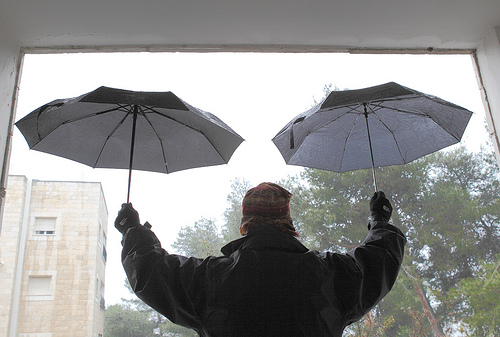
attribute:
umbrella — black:
[13, 86, 245, 226]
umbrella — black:
[270, 81, 473, 226]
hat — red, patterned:
[239, 182, 299, 238]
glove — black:
[368, 190, 394, 228]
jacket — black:
[119, 221, 406, 336]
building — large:
[0, 174, 109, 335]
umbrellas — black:
[13, 80, 474, 206]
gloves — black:
[114, 190, 393, 234]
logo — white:
[119, 216, 128, 227]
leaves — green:
[471, 279, 497, 304]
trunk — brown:
[415, 284, 447, 335]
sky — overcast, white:
[7, 51, 493, 174]